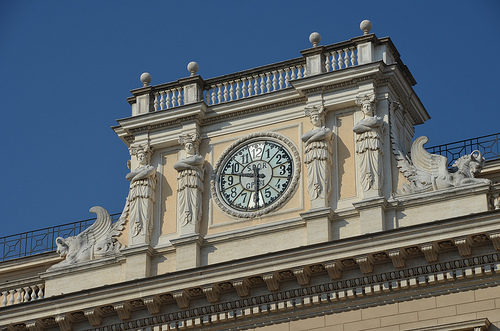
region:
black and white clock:
[217, 138, 299, 206]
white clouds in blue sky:
[31, 9, 71, 56]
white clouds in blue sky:
[47, 51, 92, 89]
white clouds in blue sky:
[31, 109, 72, 163]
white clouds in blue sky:
[14, 102, 62, 133]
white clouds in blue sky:
[41, 152, 88, 176]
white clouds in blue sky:
[85, 13, 139, 41]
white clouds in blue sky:
[434, 26, 481, 70]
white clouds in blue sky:
[441, 81, 488, 118]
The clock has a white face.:
[208, 135, 294, 205]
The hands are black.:
[228, 165, 268, 197]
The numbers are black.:
[218, 135, 298, 209]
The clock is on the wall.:
[176, 121, 320, 231]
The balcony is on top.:
[125, 18, 412, 93]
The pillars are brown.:
[103, 28, 421, 90]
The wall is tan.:
[106, 85, 400, 237]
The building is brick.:
[210, 288, 477, 330]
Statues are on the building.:
[118, 85, 409, 237]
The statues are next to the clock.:
[97, 74, 404, 254]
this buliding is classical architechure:
[16, 69, 436, 293]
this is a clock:
[216, 140, 310, 195]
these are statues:
[306, 103, 474, 236]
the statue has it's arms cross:
[345, 108, 392, 146]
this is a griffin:
[387, 137, 487, 189]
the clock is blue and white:
[211, 140, 313, 221]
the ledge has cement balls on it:
[133, 69, 161, 87]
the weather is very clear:
[26, 75, 130, 228]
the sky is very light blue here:
[19, 68, 101, 195]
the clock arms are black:
[224, 163, 269, 208]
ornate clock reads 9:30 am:
[211, 128, 298, 218]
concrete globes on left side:
[130, 58, 206, 85]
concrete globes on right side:
[301, 15, 378, 50]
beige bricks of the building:
[159, 268, 497, 328]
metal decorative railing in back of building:
[0, 124, 498, 266]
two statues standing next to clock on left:
[116, 126, 205, 250]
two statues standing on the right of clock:
[294, 87, 394, 212]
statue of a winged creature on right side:
[386, 97, 493, 199]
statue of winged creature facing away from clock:
[41, 184, 128, 279]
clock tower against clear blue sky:
[0, 1, 499, 265]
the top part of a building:
[52, 68, 453, 293]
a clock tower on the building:
[186, 122, 326, 247]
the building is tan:
[118, 117, 499, 286]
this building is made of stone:
[105, 52, 382, 137]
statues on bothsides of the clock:
[99, 84, 397, 245]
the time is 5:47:
[193, 122, 300, 229]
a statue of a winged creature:
[389, 122, 486, 202]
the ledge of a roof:
[81, 232, 476, 329]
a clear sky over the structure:
[25, 19, 475, 298]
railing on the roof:
[6, 209, 98, 266]